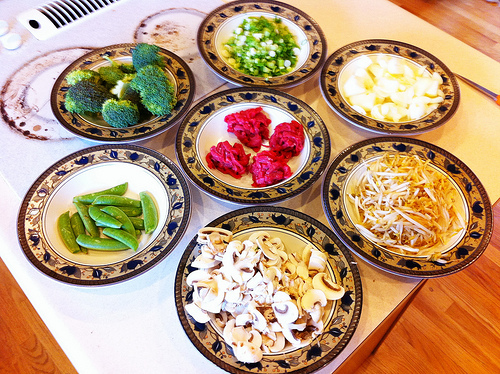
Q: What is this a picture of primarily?
A: Food.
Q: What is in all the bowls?
A: Vegetables.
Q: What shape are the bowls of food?
A: Circles.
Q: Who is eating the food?
A: No one.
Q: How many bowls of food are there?
A: Seven.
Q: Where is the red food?
A: The middle.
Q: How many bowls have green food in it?
A: Three.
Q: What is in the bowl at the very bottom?
A: Mushrooms.